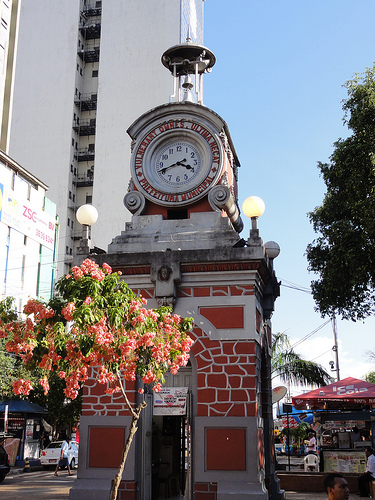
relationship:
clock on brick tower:
[141, 126, 212, 196] [66, 0, 286, 500]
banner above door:
[149, 381, 192, 414] [152, 415, 185, 498]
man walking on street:
[55, 431, 76, 476] [0, 457, 78, 496]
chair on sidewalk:
[303, 450, 321, 474] [274, 453, 325, 474]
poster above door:
[152, 386, 188, 416] [149, 418, 188, 491]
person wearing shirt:
[303, 431, 318, 458] [304, 437, 320, 450]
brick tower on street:
[66, 0, 286, 500] [2, 428, 373, 494]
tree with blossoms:
[9, 269, 164, 498] [79, 321, 184, 382]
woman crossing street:
[53, 433, 73, 475] [0, 466, 78, 498]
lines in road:
[13, 476, 72, 490] [2, 457, 87, 497]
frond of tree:
[272, 327, 337, 388] [270, 327, 337, 389]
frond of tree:
[270, 359, 336, 382] [270, 327, 337, 389]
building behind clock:
[13, 3, 213, 266] [131, 123, 215, 202]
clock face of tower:
[156, 143, 196, 181] [104, 42, 241, 243]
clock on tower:
[141, 126, 212, 196] [72, 51, 269, 497]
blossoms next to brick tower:
[0, 257, 193, 402] [66, 0, 286, 500]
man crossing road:
[53, 432, 72, 481] [2, 457, 87, 497]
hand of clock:
[175, 159, 194, 173] [146, 132, 210, 189]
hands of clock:
[157, 157, 187, 173] [155, 139, 202, 186]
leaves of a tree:
[325, 98, 355, 241] [322, 82, 365, 300]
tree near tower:
[322, 82, 365, 300] [40, 11, 213, 268]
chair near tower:
[304, 454, 320, 473] [55, 46, 300, 498]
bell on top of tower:
[182, 74, 194, 90] [67, 113, 272, 497]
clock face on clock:
[155, 138, 203, 186] [106, 20, 244, 252]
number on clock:
[183, 145, 188, 154] [155, 139, 200, 183]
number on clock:
[186, 150, 196, 158] [155, 139, 200, 183]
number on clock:
[191, 158, 199, 166] [155, 139, 200, 183]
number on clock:
[188, 166, 196, 173] [155, 139, 200, 183]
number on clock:
[170, 171, 181, 183] [155, 139, 200, 183]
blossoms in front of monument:
[0, 257, 193, 402] [69, 24, 268, 499]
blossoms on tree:
[0, 257, 193, 402] [0, 252, 201, 498]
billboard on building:
[0, 183, 57, 253] [1, 154, 63, 329]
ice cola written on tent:
[331, 385, 366, 391] [291, 367, 374, 413]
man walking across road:
[53, 432, 72, 481] [24, 456, 78, 488]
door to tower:
[127, 330, 203, 498] [118, 33, 278, 491]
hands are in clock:
[161, 160, 195, 171] [145, 136, 208, 185]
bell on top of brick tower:
[178, 72, 196, 90] [66, 0, 286, 500]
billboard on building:
[1, 184, 59, 250] [0, 151, 56, 468]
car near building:
[36, 437, 81, 475] [3, 151, 70, 498]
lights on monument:
[49, 188, 280, 251] [67, 7, 283, 498]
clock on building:
[159, 132, 204, 187] [78, 104, 275, 496]